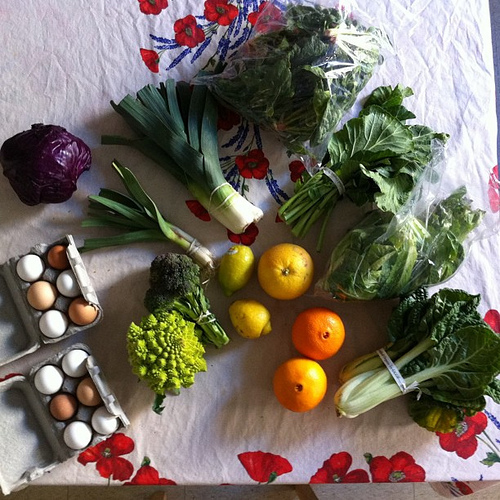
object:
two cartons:
[1, 232, 128, 494]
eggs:
[0, 235, 130, 456]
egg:
[34, 365, 64, 395]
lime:
[229, 298, 273, 339]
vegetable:
[332, 287, 500, 434]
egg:
[16, 254, 45, 283]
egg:
[26, 280, 57, 311]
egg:
[39, 310, 68, 338]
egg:
[57, 270, 81, 298]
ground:
[448, 136, 465, 157]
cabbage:
[0, 123, 93, 206]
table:
[2, 1, 498, 481]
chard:
[191, 1, 391, 177]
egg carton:
[0, 373, 60, 496]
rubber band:
[362, 350, 422, 403]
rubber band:
[202, 167, 261, 222]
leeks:
[81, 79, 264, 271]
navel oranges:
[272, 307, 345, 413]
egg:
[0, 232, 130, 495]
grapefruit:
[258, 243, 314, 300]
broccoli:
[144, 253, 231, 350]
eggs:
[34, 348, 120, 450]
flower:
[237, 449, 294, 484]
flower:
[77, 432, 135, 482]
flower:
[305, 451, 370, 484]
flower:
[369, 451, 426, 483]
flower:
[436, 410, 487, 459]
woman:
[0, 0, 499, 493]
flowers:
[173, 14, 205, 48]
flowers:
[235, 149, 270, 181]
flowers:
[369, 450, 426, 483]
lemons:
[219, 244, 273, 340]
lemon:
[229, 300, 272, 339]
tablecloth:
[16, 12, 151, 96]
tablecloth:
[3, 1, 499, 500]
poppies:
[138, 2, 289, 75]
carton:
[0, 342, 131, 499]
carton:
[0, 234, 103, 370]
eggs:
[16, 246, 99, 340]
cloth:
[0, 1, 499, 500]